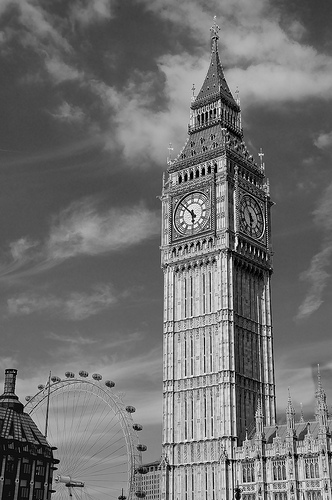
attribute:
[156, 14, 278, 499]
tower — big, tall, british, large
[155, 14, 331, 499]
building — large, old fashioned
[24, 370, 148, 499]
ferris wheel — large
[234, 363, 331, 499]
building section — old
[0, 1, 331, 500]
sky — cloudy, grey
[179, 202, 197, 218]
clock hand — black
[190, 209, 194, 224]
clock hand — black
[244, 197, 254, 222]
clock hand — black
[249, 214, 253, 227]
clock hand — black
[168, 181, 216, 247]
clock frame — square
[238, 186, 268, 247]
clock frame — square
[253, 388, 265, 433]
steeple — small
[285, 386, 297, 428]
steeple — small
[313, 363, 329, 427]
steeple — small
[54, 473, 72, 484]
center — white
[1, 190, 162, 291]
cloud — wispy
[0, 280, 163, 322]
cloud — wispy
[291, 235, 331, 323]
cloud — wispy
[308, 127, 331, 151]
cloud — wispy, small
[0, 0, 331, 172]
cloud — wispy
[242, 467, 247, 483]
window — arched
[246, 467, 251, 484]
window — arched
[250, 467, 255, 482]
window — arched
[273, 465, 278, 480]
window — arched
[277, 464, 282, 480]
window — arched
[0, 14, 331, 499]
cityscape — british